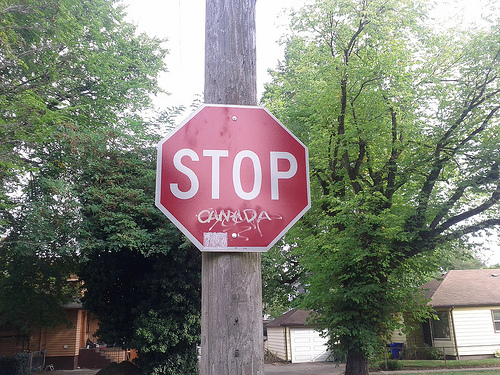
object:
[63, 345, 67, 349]
vent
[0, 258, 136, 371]
house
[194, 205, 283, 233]
words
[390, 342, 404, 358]
trash can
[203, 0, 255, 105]
pole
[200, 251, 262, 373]
pole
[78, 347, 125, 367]
steps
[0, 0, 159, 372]
tree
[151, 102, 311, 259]
sign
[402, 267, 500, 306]
house's roof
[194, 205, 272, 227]
cananda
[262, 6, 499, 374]
tree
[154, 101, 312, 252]
stop sign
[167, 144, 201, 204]
letter s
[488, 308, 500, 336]
window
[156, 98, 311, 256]
red sign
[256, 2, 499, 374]
branches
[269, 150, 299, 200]
letter p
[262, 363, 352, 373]
drive way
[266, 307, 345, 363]
garage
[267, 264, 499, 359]
house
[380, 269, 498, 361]
house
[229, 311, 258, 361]
lines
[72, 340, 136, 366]
small wall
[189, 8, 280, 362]
wooden post